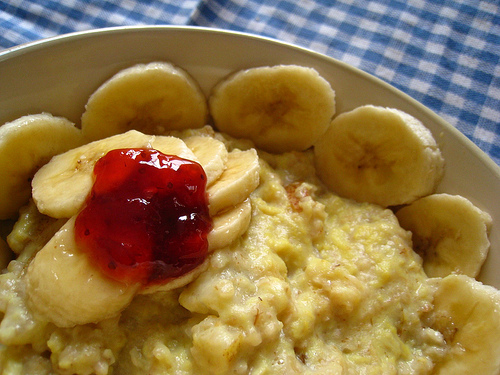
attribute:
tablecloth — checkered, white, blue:
[2, 2, 496, 178]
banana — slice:
[212, 49, 333, 164]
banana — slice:
[432, 271, 499, 373]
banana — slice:
[306, 97, 446, 217]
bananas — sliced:
[7, 67, 332, 325]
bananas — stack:
[13, 52, 292, 327]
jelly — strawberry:
[71, 145, 212, 292]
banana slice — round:
[319, 103, 444, 203]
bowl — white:
[160, 20, 341, 54]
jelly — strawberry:
[76, 146, 217, 286]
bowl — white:
[4, 27, 496, 373]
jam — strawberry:
[66, 153, 226, 281]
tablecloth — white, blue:
[357, 5, 456, 84]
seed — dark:
[265, 96, 283, 109]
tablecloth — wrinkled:
[164, 3, 234, 27]